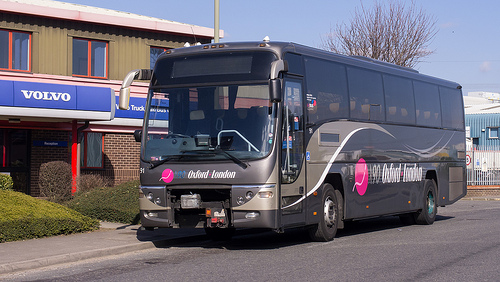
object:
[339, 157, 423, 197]
logo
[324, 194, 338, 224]
rim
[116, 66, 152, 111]
mirror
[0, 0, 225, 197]
building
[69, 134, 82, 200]
pole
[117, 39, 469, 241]
bus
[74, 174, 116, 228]
bush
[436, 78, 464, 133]
window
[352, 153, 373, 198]
logo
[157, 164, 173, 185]
logo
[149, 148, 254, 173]
windshield wipers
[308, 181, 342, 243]
tire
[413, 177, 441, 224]
tire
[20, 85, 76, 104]
logo